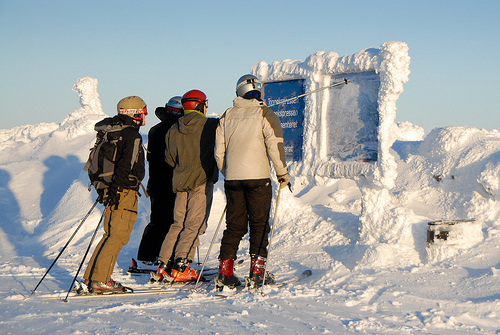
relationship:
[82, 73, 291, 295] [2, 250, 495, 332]
four people in snow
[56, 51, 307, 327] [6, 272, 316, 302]
people wearing skiis wearing skis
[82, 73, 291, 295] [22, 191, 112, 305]
four people holding ski poles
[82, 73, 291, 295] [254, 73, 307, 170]
four people looking at board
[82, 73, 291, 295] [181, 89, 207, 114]
four people wearing red helmet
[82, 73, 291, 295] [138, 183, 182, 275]
four people wearing black pants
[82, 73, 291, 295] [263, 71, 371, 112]
four people using pole to point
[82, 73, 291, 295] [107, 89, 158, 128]
four people wearing green helmet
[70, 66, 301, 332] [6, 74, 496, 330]
four people standing in snow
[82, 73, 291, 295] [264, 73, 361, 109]
four people pointing with ski pole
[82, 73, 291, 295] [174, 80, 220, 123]
four people wearing red helmet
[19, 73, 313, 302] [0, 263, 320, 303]
people wearing skiis wearing skis